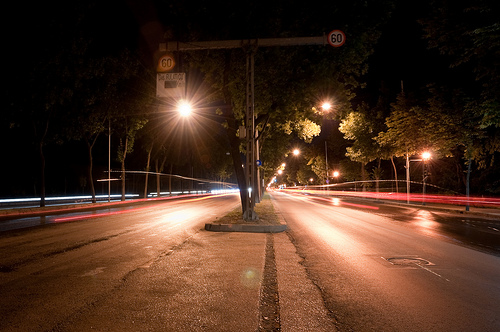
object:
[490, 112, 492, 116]
leaves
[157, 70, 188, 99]
sign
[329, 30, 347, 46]
sign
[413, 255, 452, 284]
line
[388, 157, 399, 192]
branches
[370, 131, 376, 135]
leaves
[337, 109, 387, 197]
tree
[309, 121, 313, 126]
leaf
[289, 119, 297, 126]
leaf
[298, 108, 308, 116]
leaf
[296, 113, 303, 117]
leaf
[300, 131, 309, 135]
leaf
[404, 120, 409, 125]
leaves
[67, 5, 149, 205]
tree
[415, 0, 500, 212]
tree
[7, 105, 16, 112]
leaves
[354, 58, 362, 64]
leaves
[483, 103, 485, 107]
leaves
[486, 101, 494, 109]
leaves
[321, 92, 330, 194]
pole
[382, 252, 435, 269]
sewer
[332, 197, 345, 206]
light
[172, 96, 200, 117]
light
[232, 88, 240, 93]
leaves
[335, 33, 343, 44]
number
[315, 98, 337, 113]
light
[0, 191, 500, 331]
street